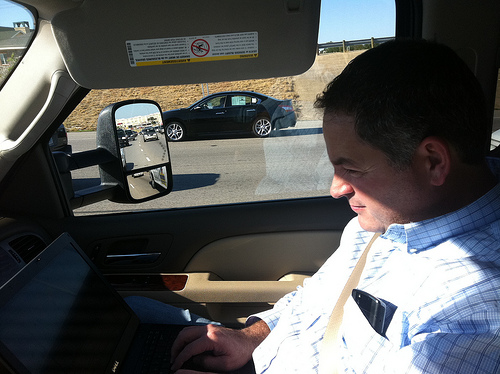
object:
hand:
[167, 316, 253, 371]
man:
[120, 39, 498, 369]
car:
[140, 124, 160, 144]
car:
[152, 125, 161, 134]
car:
[116, 128, 130, 149]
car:
[123, 129, 138, 141]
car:
[147, 161, 167, 190]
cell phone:
[349, 286, 388, 334]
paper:
[230, 96, 246, 106]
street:
[61, 119, 336, 217]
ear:
[416, 137, 451, 187]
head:
[320, 33, 489, 227]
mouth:
[344, 200, 367, 213]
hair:
[310, 39, 494, 174]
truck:
[3, 1, 499, 371]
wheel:
[161, 121, 186, 145]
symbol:
[189, 36, 211, 59]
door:
[68, 189, 364, 328]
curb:
[64, 121, 329, 142]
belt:
[320, 229, 386, 346]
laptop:
[0, 230, 233, 371]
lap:
[124, 290, 172, 326]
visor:
[49, 0, 321, 92]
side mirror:
[112, 102, 174, 202]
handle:
[104, 248, 166, 262]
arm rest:
[160, 271, 317, 306]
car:
[156, 90, 298, 144]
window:
[195, 94, 227, 109]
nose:
[328, 175, 354, 202]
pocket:
[329, 297, 386, 373]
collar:
[376, 196, 495, 254]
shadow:
[320, 109, 500, 220]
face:
[319, 110, 439, 233]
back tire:
[249, 118, 274, 138]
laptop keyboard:
[112, 322, 240, 374]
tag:
[123, 30, 260, 70]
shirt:
[242, 184, 499, 372]